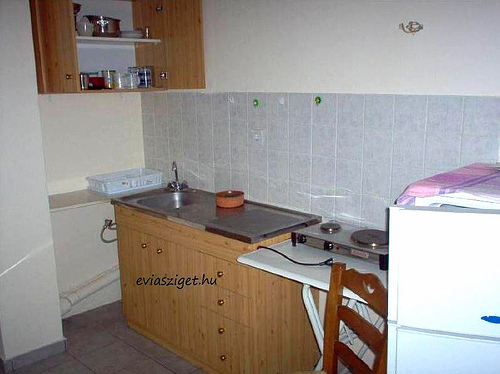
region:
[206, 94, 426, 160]
gray tile backsplash on wall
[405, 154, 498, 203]
pink and purple blanket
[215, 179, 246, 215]
orange bowl on top of counter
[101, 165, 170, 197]
white bin on top of shelf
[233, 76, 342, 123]
two green magnets on wall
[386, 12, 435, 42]
silver hook on wall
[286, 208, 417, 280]
silver burner on table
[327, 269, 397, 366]
wooden designed chair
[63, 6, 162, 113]
cabinet with two shelves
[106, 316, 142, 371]
brown colored kitchen tile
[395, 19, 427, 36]
hook hanging on wall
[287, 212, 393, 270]
electrical hot plate on counter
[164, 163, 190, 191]
diagonal kitchen faucet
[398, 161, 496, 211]
cloth covering something on refrigerator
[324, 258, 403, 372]
back of a kitchen chair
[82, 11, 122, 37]
medium sized pot in cabinet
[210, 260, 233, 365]
bronze drawer pulls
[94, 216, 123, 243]
water piping with valve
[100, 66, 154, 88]
drinking glasses in cabinet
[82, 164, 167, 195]
white dish drainer on shelf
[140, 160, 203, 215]
A sink of the counter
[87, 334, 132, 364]
Grey tiled floor in the room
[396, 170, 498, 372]
A white fridge by the wall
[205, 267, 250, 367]
Drawers beneath the counter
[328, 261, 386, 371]
A brown chair by the refrigerator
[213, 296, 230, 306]
A handle of the drawer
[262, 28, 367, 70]
The white area of the wall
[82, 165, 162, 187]
A white basket by the sink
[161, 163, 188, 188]
The faucet of the sink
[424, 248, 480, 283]
The refridgerator is white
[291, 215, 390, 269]
silver portable stove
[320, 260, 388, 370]
back of a wood chair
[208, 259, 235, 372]
four copper knobs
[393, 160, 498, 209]
a towel laid out on top a fridge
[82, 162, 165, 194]
white plastic dish rack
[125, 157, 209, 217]
silver water spout and sink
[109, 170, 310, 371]
wood cabinets under the sink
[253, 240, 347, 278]
black plug in laying on the table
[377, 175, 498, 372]
fridge and freezer door slightly open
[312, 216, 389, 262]
two burners used for cooking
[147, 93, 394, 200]
A tiled backsplash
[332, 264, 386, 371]
The chair is wooden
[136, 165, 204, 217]
The sink is metal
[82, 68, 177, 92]
Containers on a shelf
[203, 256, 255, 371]
Four drawers stacked up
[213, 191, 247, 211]
A bowl on the counter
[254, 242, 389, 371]
A folding white table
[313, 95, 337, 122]
A green circle in the left corner of a tile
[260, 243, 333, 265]
A black electrical cord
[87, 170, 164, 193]
A white dish rack